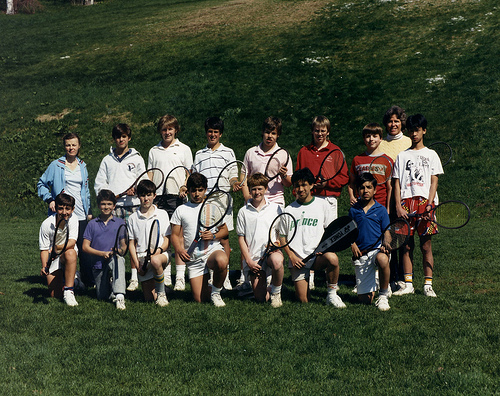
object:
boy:
[94, 122, 150, 222]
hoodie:
[94, 146, 147, 196]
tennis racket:
[116, 167, 165, 200]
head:
[311, 115, 329, 144]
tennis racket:
[44, 217, 70, 271]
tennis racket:
[314, 148, 346, 185]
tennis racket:
[264, 147, 289, 179]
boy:
[348, 171, 393, 312]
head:
[403, 114, 427, 142]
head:
[358, 173, 377, 201]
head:
[136, 179, 157, 208]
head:
[55, 193, 76, 220]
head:
[290, 169, 313, 199]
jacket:
[36, 156, 91, 218]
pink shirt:
[241, 142, 294, 201]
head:
[158, 114, 181, 142]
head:
[257, 116, 283, 147]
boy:
[93, 123, 150, 206]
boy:
[146, 114, 193, 202]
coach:
[34, 133, 93, 236]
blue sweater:
[37, 156, 91, 215]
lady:
[378, 106, 413, 164]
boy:
[193, 116, 245, 291]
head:
[111, 122, 132, 149]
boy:
[239, 117, 294, 206]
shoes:
[325, 292, 348, 308]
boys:
[168, 171, 229, 309]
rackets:
[177, 160, 249, 261]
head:
[96, 189, 118, 215]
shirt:
[392, 147, 444, 206]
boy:
[124, 178, 172, 306]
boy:
[38, 193, 79, 307]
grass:
[1, 0, 497, 394]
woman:
[35, 132, 95, 289]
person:
[35, 133, 93, 286]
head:
[362, 121, 384, 149]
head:
[288, 165, 318, 200]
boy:
[392, 114, 444, 298]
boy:
[82, 189, 129, 311]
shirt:
[82, 214, 125, 269]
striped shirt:
[192, 143, 238, 194]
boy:
[292, 114, 349, 217]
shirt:
[292, 141, 350, 197]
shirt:
[349, 200, 391, 251]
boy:
[279, 167, 347, 309]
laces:
[214, 296, 222, 302]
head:
[186, 172, 209, 203]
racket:
[251, 213, 297, 278]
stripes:
[195, 155, 229, 172]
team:
[35, 104, 446, 311]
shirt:
[38, 212, 79, 255]